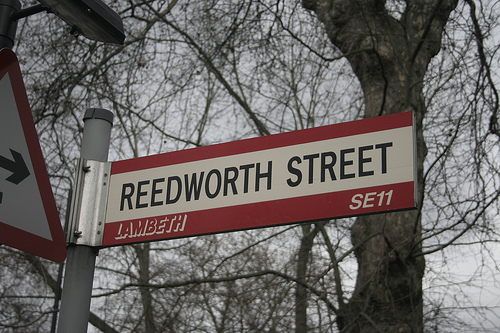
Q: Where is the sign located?
A: In the street.